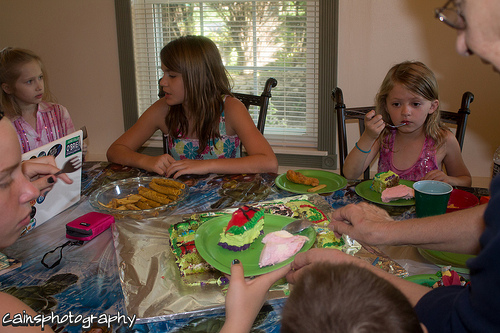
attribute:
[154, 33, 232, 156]
hair — brown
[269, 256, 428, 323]
head — PERSON'S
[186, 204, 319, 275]
plate — GREEN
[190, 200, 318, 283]
plate — GREEN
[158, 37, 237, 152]
hair — LONG, BROWN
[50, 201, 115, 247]
bag — PINK, CAMERA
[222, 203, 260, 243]
frosting — RED, GREEN